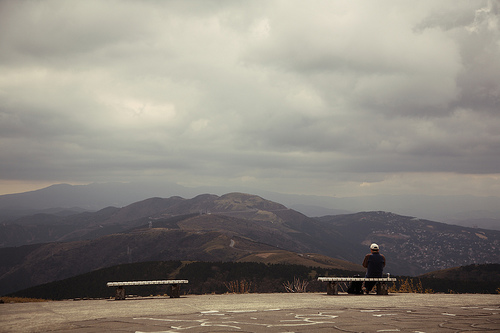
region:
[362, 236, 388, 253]
the hat is white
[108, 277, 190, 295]
the bench is white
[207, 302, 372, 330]
the floor has drawing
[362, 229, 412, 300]
the guy is sitted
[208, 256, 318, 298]
the hill has trees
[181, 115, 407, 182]
the sky is cloudy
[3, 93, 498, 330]
the scene is ooutdoors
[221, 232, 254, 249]
the road is on the hill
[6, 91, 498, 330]
the weather is gloomy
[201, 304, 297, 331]
the drawings are white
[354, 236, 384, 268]
this is a man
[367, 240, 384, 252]
this is a cap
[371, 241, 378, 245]
the cap is white in color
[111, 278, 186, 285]
this is a bench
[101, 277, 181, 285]
the bench is white in color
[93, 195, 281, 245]
this is a mountain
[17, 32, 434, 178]
this is the sky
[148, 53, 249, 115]
these are the clouds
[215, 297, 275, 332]
this is a bare ground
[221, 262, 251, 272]
these are the trees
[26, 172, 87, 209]
This is a hill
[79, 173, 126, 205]
This is a hill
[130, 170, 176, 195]
This is a hill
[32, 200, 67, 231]
This is a hill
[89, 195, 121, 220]
This is a hill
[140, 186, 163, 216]
This is a hill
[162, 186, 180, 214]
This is a hill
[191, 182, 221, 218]
This is a hill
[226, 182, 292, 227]
This is a hill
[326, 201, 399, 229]
This is a hill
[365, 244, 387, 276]
person sitting on a bench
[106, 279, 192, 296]
a bench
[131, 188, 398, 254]
the mountains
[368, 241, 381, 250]
person wearing a hat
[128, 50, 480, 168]
the clouds in the sky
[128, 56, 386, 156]
the clouds are grey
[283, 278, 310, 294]
tree branches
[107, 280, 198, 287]
the bench is white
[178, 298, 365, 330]
the ground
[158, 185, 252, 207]
the top of the mountain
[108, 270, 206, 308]
the bench is white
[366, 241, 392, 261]
the hat iswhite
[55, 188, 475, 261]
hills are in the background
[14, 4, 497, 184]
the sky is cloudy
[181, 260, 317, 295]
the hill is covered with trees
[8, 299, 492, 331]
the surface is stoned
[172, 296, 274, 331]
white drawings are on the surface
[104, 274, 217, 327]
the bench has two legs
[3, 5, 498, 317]
the scene is outdoors